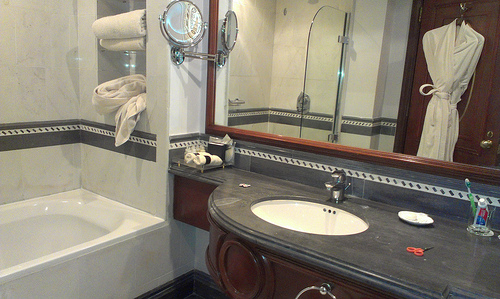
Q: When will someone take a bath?
A: When the tub is full.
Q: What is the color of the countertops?
A: Grey.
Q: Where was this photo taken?
A: Hotel bathroom.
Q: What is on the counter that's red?
A: Scissors.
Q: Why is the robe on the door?
A: So someone can grab it after stepping out of the shower.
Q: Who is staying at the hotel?
A: A man.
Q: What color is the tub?
A: White.